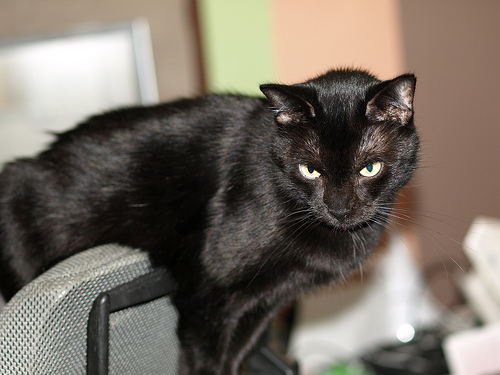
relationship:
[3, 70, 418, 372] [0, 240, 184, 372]
cat on grey chair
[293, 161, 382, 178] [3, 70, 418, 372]
green eyes on cat